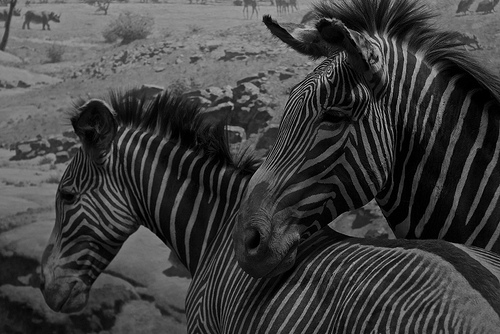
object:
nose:
[230, 180, 275, 268]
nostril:
[242, 227, 264, 255]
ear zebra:
[69, 97, 117, 161]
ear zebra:
[313, 17, 391, 90]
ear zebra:
[259, 12, 330, 61]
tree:
[0, 0, 18, 51]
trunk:
[1, 0, 22, 16]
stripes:
[146, 136, 248, 303]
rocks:
[198, 66, 278, 144]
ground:
[161, 23, 265, 72]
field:
[0, 0, 309, 157]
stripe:
[354, 120, 394, 163]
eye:
[316, 107, 346, 132]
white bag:
[35, 85, 240, 313]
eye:
[59, 191, 77, 205]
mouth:
[258, 240, 300, 279]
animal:
[19, 9, 61, 32]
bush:
[101, 10, 157, 44]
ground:
[35, 30, 131, 90]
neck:
[123, 124, 245, 271]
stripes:
[301, 275, 433, 327]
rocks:
[75, 36, 273, 72]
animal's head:
[32, 98, 144, 314]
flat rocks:
[1, 172, 194, 333]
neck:
[376, 60, 499, 243]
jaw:
[283, 183, 342, 223]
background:
[164, 10, 250, 44]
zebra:
[236, 0, 500, 279]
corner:
[51, 9, 67, 19]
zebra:
[36, 79, 500, 333]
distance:
[1, 0, 500, 45]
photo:
[0, 0, 499, 333]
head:
[231, 13, 396, 279]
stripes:
[266, 103, 412, 198]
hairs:
[106, 83, 261, 170]